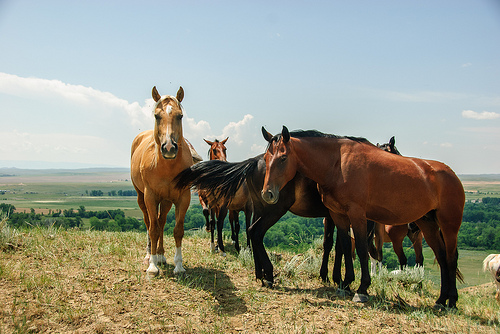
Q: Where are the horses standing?
A: On a hill.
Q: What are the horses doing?
A: Standing.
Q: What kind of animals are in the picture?
A: Horses.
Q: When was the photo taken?
A: Daytime.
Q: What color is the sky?
A: Blue.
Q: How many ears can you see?
A: Seven.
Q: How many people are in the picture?
A: None.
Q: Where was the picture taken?
A: At a house farm.